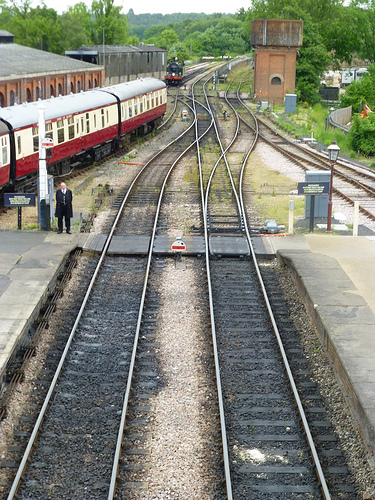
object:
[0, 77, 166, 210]
train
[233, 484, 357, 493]
plank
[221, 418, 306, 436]
plank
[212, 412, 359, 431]
plank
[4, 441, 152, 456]
plank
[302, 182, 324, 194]
sign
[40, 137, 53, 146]
sign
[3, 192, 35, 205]
sign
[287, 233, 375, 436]
platform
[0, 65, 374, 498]
gravel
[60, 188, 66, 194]
white shirt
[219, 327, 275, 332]
tie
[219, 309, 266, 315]
tie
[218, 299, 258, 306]
tie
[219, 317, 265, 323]
tie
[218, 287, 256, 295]
tie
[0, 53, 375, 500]
rail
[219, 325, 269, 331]
wood plank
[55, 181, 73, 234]
man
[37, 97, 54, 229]
pole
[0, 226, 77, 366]
pavement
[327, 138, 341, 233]
post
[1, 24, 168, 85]
rural railroad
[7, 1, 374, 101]
trees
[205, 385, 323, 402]
wood plank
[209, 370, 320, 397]
wood plank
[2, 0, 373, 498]
railroad station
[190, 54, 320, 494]
track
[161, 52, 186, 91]
train car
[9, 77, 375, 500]
train track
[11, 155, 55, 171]
trim